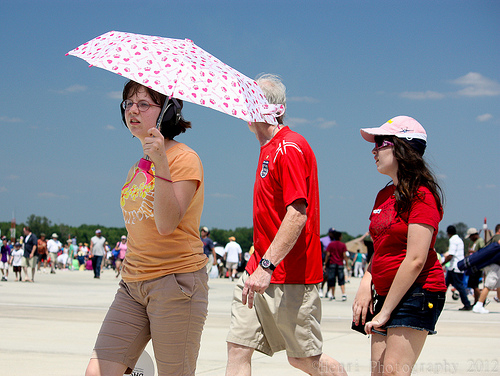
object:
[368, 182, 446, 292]
red shirt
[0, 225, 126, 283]
crowd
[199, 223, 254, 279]
crowd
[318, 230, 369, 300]
crowd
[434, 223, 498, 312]
crowd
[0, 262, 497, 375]
ground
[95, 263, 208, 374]
short pant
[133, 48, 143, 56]
hearts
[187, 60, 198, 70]
hearts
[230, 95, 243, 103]
hearts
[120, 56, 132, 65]
hearts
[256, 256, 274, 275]
watch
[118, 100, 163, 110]
glasses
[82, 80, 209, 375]
woman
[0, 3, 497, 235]
sky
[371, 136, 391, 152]
sunglasses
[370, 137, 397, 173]
girl's face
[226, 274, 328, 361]
tan shorts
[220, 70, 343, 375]
man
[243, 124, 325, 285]
shirt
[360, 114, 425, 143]
cap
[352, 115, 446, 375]
girl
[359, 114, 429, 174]
head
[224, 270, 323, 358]
shorts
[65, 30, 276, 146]
umbrella